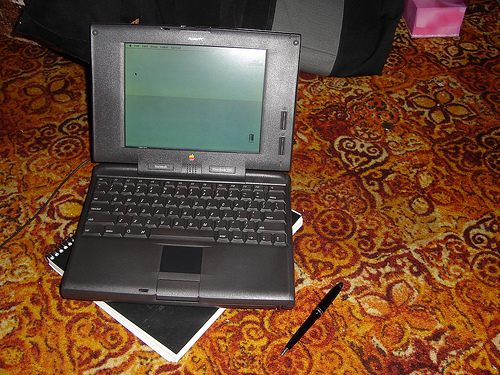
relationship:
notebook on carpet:
[120, 307, 221, 352] [337, 162, 481, 272]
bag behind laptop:
[9, 0, 418, 82] [59, 21, 301, 308]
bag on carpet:
[9, 0, 418, 82] [1, 7, 496, 373]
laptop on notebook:
[81, 31, 298, 295] [47, 208, 304, 366]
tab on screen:
[132, 42, 142, 48] [120, 41, 267, 154]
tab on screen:
[139, 43, 150, 48] [120, 41, 267, 154]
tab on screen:
[148, 45, 159, 49] [120, 41, 267, 154]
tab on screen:
[160, 45, 170, 49] [120, 41, 267, 154]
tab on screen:
[168, 44, 181, 50] [120, 41, 267, 154]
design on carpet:
[415, 88, 467, 124] [326, 102, 475, 184]